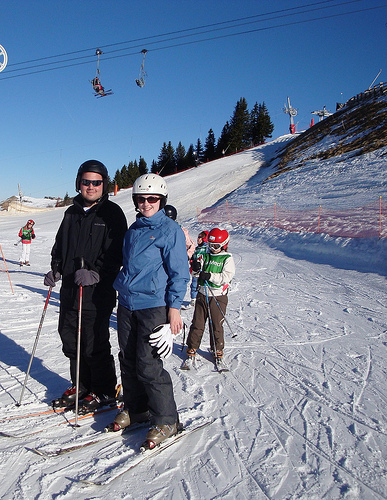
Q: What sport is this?
A: Skiing.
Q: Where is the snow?
A: On the ground.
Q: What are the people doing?
A: They are skiing.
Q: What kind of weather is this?
A: Winter.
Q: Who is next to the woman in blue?
A: The guy in black helmet.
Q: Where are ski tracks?
A: On the snow.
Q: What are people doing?
A: Skiing.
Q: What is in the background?
A: Trees.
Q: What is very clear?
A: The sky.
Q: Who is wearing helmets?
A: The skiers.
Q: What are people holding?
A: Ski poles.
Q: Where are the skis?
A: Under the skier's feet.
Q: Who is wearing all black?
A: The man on the left.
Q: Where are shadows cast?
A: On the snow.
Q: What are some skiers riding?
A: A ski lift.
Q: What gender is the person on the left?
A: Male.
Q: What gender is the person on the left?
A: Female.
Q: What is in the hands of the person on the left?
A: Ski poles.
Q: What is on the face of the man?
A: Sunglasses.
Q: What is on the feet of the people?
A: Skis.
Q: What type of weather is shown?
A: Clear.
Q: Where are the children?
A: Behind the adults.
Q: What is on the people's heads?
A: Helmets.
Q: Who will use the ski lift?
A: People.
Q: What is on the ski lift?
A: People.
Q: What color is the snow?
A: White.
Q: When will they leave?
A: Soon.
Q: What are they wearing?
A: Jackets.